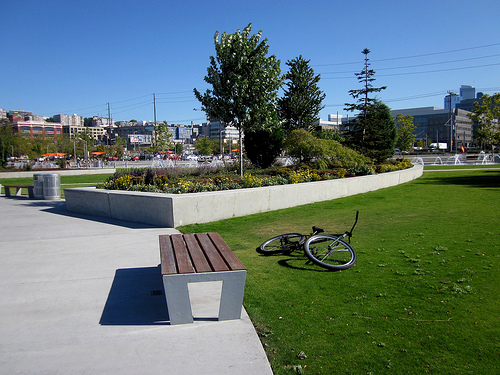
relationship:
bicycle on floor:
[255, 207, 362, 274] [194, 164, 498, 374]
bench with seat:
[155, 230, 253, 323] [155, 230, 246, 277]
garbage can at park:
[40, 172, 62, 203] [1, 24, 496, 366]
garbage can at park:
[31, 174, 43, 201] [1, 24, 496, 366]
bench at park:
[144, 230, 254, 323] [146, 215, 304, 305]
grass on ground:
[260, 189, 497, 366] [226, 191, 484, 371]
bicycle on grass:
[255, 207, 362, 274] [172, 161, 496, 371]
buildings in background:
[2, 83, 497, 158] [2, 67, 496, 168]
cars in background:
[101, 129, 227, 186] [3, 6, 482, 169]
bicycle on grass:
[251, 207, 361, 273] [172, 161, 496, 371]